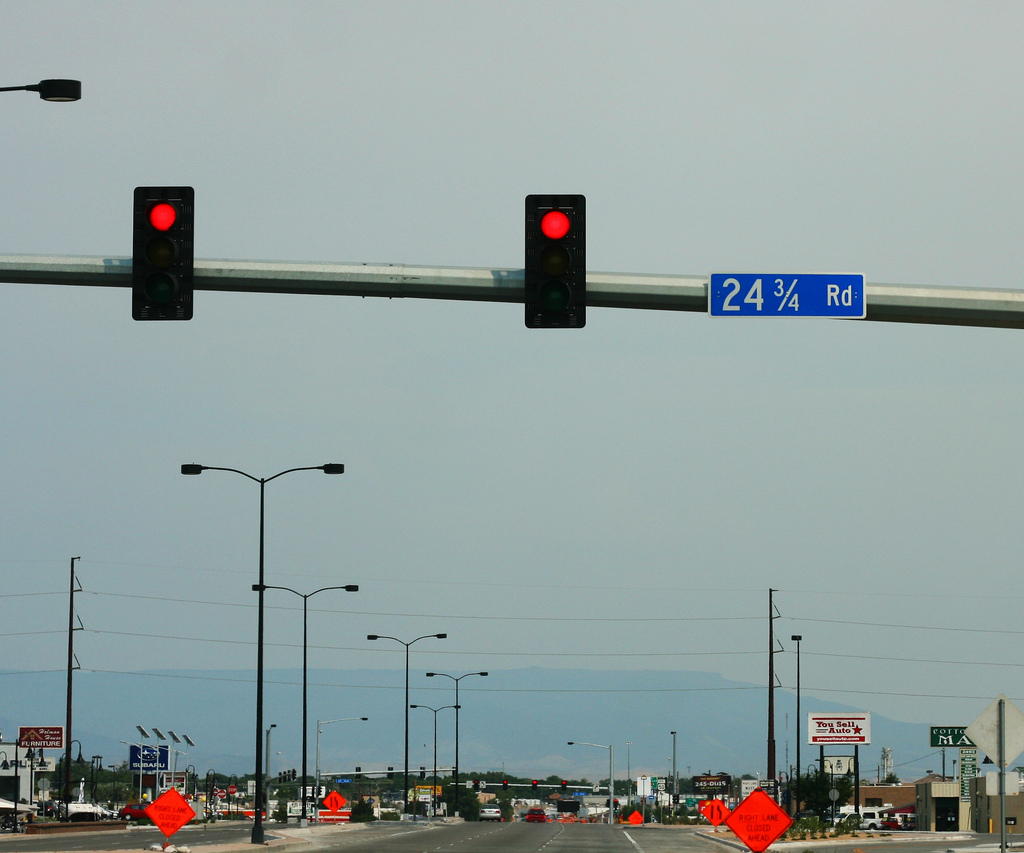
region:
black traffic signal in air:
[123, 183, 210, 333]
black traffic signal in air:
[521, 187, 599, 331]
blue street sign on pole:
[713, 263, 870, 325]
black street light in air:
[0, 64, 98, 132]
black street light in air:
[305, 443, 354, 497]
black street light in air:
[169, 449, 208, 487]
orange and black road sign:
[141, 772, 221, 849]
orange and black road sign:
[315, 778, 354, 824]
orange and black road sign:
[719, 780, 805, 850]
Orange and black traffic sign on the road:
[713, 780, 799, 851]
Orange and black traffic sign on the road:
[697, 793, 724, 826]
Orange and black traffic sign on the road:
[622, 808, 651, 834]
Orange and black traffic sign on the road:
[313, 786, 352, 816]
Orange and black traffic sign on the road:
[141, 784, 200, 842]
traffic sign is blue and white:
[695, 268, 872, 320]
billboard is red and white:
[802, 707, 870, 752]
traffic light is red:
[503, 189, 601, 307]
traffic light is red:
[123, 173, 206, 320]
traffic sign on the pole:
[958, 689, 1017, 773]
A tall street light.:
[182, 444, 360, 824]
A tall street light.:
[239, 548, 361, 808]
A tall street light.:
[252, 716, 290, 814]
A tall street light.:
[305, 705, 386, 807]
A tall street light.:
[367, 617, 448, 795]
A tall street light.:
[422, 664, 492, 791]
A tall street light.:
[401, 691, 463, 791]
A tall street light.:
[565, 721, 622, 813]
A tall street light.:
[786, 630, 809, 776]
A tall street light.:
[663, 724, 690, 800]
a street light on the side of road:
[208, 479, 286, 852]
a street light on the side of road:
[239, 550, 309, 743]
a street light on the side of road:
[347, 594, 436, 760]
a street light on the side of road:
[454, 645, 471, 745]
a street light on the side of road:
[404, 680, 478, 785]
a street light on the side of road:
[370, 680, 447, 807]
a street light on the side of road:
[226, 673, 303, 795]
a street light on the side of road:
[555, 699, 619, 799]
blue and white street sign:
[693, 243, 902, 326]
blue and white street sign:
[678, 247, 893, 337]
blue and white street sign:
[664, 228, 890, 352]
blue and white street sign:
[677, 237, 890, 354]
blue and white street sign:
[671, 236, 881, 344]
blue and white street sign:
[691, 250, 923, 339]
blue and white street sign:
[697, 250, 879, 327]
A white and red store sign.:
[802, 696, 876, 747]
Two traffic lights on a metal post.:
[43, 159, 1011, 346]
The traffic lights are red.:
[111, 180, 624, 337]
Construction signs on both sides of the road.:
[150, 760, 815, 843]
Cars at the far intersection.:
[456, 790, 562, 830]